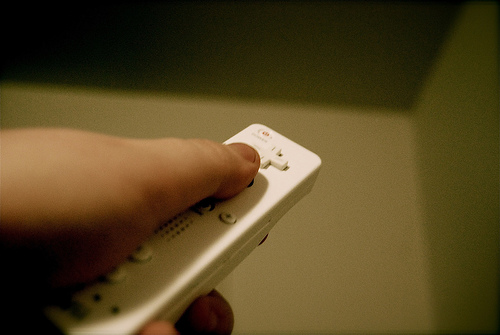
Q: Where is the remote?
A: In the hand.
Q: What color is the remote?
A: White.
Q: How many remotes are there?
A: One.